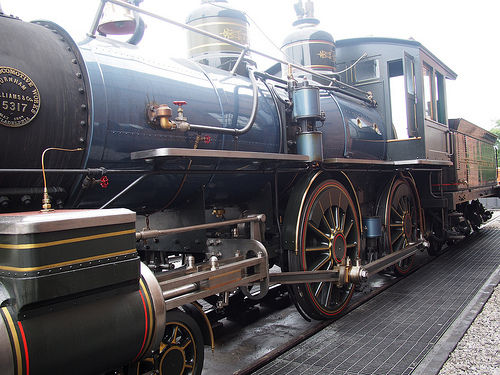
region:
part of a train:
[251, 142, 277, 170]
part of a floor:
[379, 303, 416, 348]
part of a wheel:
[316, 290, 344, 317]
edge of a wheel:
[290, 289, 328, 342]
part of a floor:
[378, 315, 398, 336]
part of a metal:
[300, 260, 327, 288]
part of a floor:
[383, 291, 407, 331]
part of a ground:
[462, 337, 488, 365]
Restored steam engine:
[2, 6, 494, 371]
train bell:
[85, 1, 152, 42]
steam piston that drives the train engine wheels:
[3, 208, 264, 373]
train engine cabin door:
[383, 56, 420, 146]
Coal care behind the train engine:
[445, 114, 498, 242]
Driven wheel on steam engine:
[298, 179, 363, 321]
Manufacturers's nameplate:
[0, 62, 48, 137]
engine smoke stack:
[270, 1, 346, 84]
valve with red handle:
[170, 98, 194, 135]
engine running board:
[135, 143, 424, 173]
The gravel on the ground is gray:
[443, 294, 498, 374]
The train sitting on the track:
[0, 2, 498, 373]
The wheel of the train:
[281, 166, 368, 324]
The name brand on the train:
[0, 64, 42, 130]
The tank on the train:
[276, 0, 341, 85]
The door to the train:
[383, 48, 423, 144]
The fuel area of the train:
[85, 28, 281, 206]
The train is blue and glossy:
[82, 22, 462, 205]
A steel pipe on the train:
[91, 0, 370, 103]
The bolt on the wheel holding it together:
[338, 255, 373, 290]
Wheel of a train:
[284, 158, 371, 330]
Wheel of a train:
[369, 159, 437, 281]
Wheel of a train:
[136, 288, 221, 372]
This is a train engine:
[15, 0, 472, 366]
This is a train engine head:
[256, 3, 471, 261]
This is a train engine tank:
[278, 0, 341, 103]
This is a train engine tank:
[179, 0, 261, 79]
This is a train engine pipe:
[129, 10, 399, 95]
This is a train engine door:
[386, 48, 421, 148]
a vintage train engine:
[12, 6, 452, 373]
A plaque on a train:
[2, 58, 42, 133]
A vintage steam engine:
[13, 2, 453, 374]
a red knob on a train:
[169, 95, 190, 116]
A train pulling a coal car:
[263, 11, 499, 268]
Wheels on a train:
[246, 165, 450, 311]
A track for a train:
[198, 308, 329, 373]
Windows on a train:
[412, 50, 452, 130]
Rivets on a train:
[30, 11, 95, 151]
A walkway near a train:
[304, 208, 498, 373]